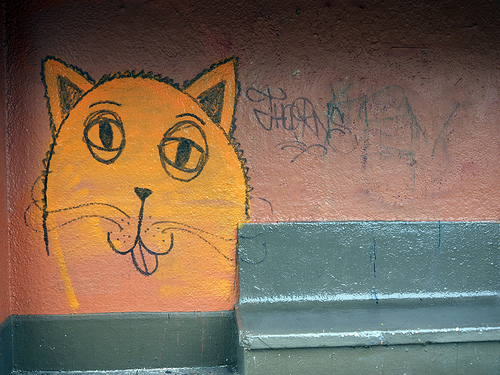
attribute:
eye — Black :
[84, 110, 124, 161]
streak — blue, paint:
[363, 231, 385, 281]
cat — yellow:
[25, 48, 237, 305]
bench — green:
[231, 220, 498, 374]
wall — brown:
[9, 5, 498, 312]